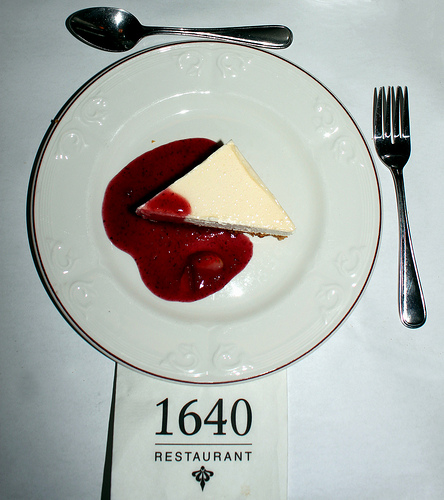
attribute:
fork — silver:
[373, 84, 428, 328]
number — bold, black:
[229, 398, 251, 436]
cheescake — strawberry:
[133, 139, 298, 235]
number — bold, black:
[151, 391, 175, 440]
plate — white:
[158, 338, 254, 380]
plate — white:
[57, 51, 370, 352]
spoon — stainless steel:
[59, 4, 295, 53]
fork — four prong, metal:
[365, 79, 432, 330]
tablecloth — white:
[5, 5, 442, 498]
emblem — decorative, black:
[184, 464, 221, 496]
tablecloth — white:
[13, 346, 89, 470]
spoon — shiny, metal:
[59, 6, 298, 61]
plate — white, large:
[22, 46, 392, 389]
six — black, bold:
[180, 398, 202, 436]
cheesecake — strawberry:
[134, 140, 293, 237]